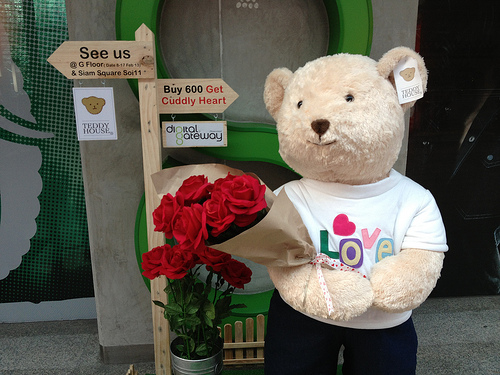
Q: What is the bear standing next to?
A: Roses.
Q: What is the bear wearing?
A: A shirt.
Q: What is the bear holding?
A: Flowers.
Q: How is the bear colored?
A: Tan.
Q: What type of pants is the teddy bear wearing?
A: Jeans.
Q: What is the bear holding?
A: Flowers.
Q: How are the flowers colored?
A: Red.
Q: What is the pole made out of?
A: Wood.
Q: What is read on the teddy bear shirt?
A: Love.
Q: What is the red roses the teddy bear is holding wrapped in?
A: Paper.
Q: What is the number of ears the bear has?
A: Two.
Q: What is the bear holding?
A: Flowers.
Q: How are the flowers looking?
A: Red.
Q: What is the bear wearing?
A: Shirt.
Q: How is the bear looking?
A: Tan.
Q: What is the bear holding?
A: Roses.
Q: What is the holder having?
A: Roses.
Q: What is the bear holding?
A: Roses.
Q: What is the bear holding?
A: Flowers.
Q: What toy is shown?
A: A teddy bear.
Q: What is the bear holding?
A: Flowers.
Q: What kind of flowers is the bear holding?
A: Rose.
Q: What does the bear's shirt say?
A: Love.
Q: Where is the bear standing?
A: On a sidewalk.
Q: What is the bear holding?
A: Roses.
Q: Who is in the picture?
A: Cuddly Heart Bear.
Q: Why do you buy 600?
A: Get Cuddly Heart.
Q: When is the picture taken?
A: During the day.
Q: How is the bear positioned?
A: Standing.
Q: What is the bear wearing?
A: A T-Shirt.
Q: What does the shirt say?
A: Love.